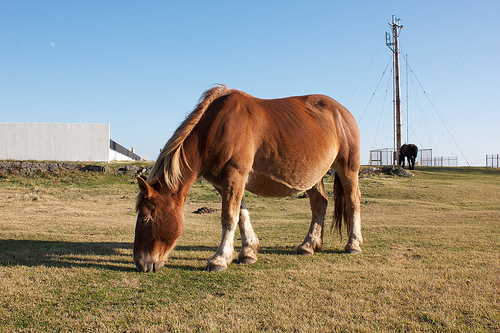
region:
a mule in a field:
[99, 91, 380, 279]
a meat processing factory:
[2, 114, 140, 165]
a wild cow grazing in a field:
[387, 134, 429, 175]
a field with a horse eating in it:
[3, 78, 498, 330]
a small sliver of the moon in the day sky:
[39, 33, 64, 60]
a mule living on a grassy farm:
[107, 81, 375, 288]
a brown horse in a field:
[128, 83, 365, 273]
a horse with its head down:
[125, 92, 222, 282]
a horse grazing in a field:
[118, 100, 213, 277]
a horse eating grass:
[392, 142, 422, 172]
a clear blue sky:
[37, 10, 311, 61]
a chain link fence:
[425, 155, 464, 170]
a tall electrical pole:
[383, 12, 409, 168]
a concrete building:
[8, 117, 113, 165]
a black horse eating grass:
[397, 142, 422, 168]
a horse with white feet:
[206, 196, 260, 274]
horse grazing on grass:
[123, 83, 366, 281]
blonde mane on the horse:
[155, 87, 225, 189]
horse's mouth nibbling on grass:
[138, 254, 163, 270]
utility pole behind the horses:
[384, 15, 406, 162]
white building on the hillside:
[2, 119, 141, 169]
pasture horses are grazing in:
[0, 159, 490, 331]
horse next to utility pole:
[391, 141, 417, 166]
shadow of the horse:
[6, 229, 306, 279]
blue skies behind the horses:
[3, 3, 495, 163]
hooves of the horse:
[204, 234, 361, 276]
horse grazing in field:
[120, 84, 370, 278]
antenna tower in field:
[380, 13, 412, 175]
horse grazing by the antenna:
[389, 142, 421, 171]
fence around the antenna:
[367, 143, 433, 171]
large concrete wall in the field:
[2, 111, 120, 169]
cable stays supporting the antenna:
[343, 48, 468, 185]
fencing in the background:
[430, 153, 499, 173]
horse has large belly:
[125, 82, 368, 278]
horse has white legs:
[194, 208, 382, 271]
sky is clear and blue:
[2, 5, 493, 132]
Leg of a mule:
[331, 151, 375, 275]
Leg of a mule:
[295, 177, 340, 279]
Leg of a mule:
[235, 194, 273, 284]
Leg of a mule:
[202, 182, 242, 287]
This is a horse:
[121, 73, 370, 287]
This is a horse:
[395, 137, 426, 182]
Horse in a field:
[98, 78, 410, 280]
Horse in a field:
[393, 137, 420, 174]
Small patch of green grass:
[26, 286, 60, 321]